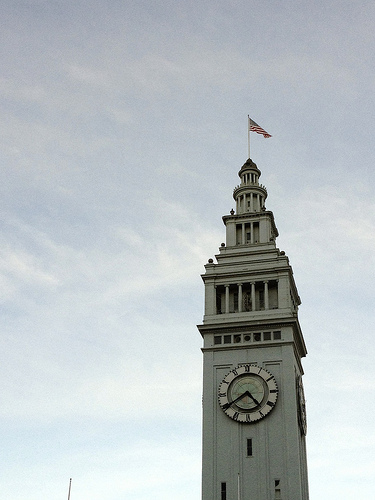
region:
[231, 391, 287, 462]
this is a tower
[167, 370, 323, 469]
this is a clock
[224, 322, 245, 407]
the clock is round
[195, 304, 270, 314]
this is a window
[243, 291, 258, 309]
this is a column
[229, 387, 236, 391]
this is a hand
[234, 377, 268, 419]
this is a roman numeral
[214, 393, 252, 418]
the hand is black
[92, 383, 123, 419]
this is a cloud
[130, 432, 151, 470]
the cloud is white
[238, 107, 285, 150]
flag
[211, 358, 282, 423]
clock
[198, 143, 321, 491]
white clock tower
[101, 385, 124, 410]
white clouds in blue sky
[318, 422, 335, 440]
white clouds in blue sky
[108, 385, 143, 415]
white clouds in blue sky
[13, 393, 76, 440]
white clouds in blue sky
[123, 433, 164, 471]
white clouds in blue sky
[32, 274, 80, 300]
white clouds in blue sky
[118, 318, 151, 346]
white clouds in blue sky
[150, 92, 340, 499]
a tall stone building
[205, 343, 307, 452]
a clock on the building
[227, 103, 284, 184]
an american flag on top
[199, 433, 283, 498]
three windows under clock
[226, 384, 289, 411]
black hands on the clock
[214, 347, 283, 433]
roman numerals on the clock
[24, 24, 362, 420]
white clouds in the sky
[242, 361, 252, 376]
Roman numeral 12 on clock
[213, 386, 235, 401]
roman numeral 9 on clock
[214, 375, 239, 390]
roman numeral 10 on clock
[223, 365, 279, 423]
the tower has a clock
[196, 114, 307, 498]
the tower is tall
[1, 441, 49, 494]
part of the cloudy sky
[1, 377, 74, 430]
part of the cloudy sky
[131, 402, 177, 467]
part of the cloudy sky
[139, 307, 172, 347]
part of the cloudy sky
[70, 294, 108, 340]
part of the cloudy sky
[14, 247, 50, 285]
part of the cloudy sky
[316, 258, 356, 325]
part of the cloudy sky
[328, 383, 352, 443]
part of the cloudy sky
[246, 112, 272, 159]
Flag on top of a structure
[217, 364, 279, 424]
Clock on the side of a tower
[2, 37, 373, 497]
Clouds in a blue sky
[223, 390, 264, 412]
Hour and minute hands on a clock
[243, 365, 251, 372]
Black numerals on a clock face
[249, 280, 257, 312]
Columns on a tower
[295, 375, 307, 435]
Clock on the side of a tower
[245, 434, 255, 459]
Small window on a tower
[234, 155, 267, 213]
Top of a tower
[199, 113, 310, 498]
A tower with clocks on it's sides